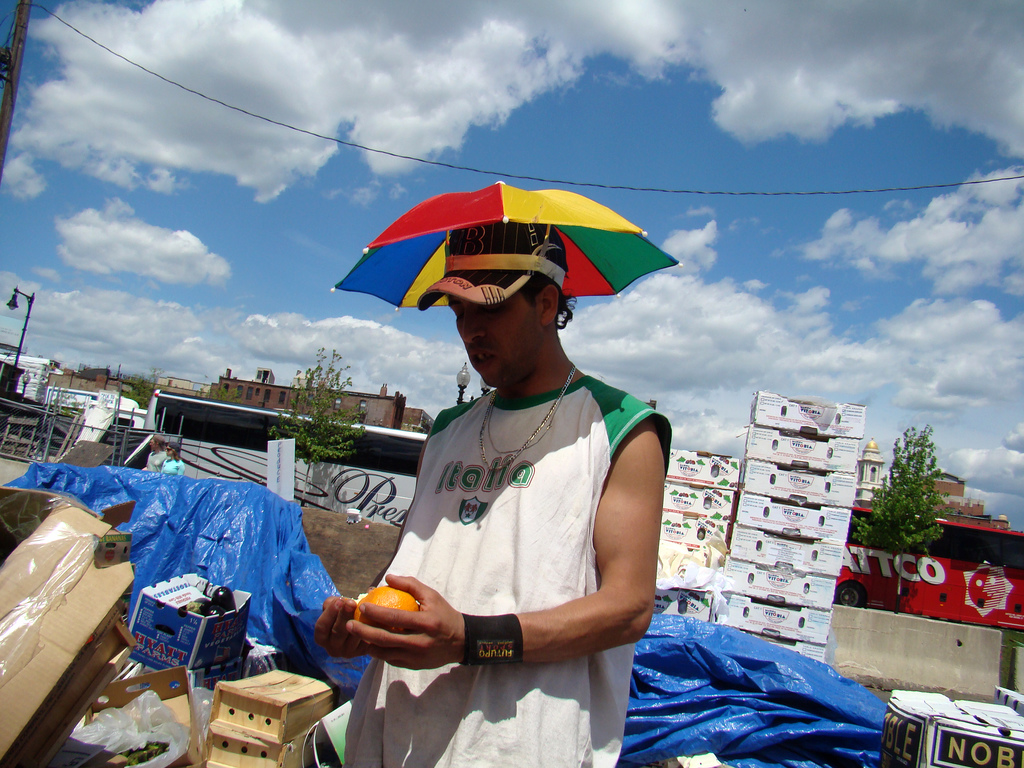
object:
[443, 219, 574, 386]
head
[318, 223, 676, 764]
man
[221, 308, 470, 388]
clouds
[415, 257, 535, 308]
visor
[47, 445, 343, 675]
tarp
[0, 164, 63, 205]
clouds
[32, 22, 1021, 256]
sky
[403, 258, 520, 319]
bill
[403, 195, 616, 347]
man's hat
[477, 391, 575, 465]
necklace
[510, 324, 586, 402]
neck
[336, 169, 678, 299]
umbrella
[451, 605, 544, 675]
wristband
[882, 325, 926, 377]
clouds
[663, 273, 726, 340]
clouds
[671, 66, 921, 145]
clouds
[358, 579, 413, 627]
orange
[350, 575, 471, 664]
hand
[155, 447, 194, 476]
people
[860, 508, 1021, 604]
bus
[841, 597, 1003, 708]
barriers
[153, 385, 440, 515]
bus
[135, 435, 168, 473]
people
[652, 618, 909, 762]
tarps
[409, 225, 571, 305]
hat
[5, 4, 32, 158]
pole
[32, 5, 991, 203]
wire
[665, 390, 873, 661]
pile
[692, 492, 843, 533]
boxes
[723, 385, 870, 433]
supplies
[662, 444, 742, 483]
supplies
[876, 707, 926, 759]
signing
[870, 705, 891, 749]
letters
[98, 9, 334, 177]
clouds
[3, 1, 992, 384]
sky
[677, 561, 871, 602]
boxes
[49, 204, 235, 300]
clouds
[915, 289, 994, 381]
clouds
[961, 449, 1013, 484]
clouds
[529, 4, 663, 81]
clouds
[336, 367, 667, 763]
top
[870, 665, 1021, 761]
box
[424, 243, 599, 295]
strap